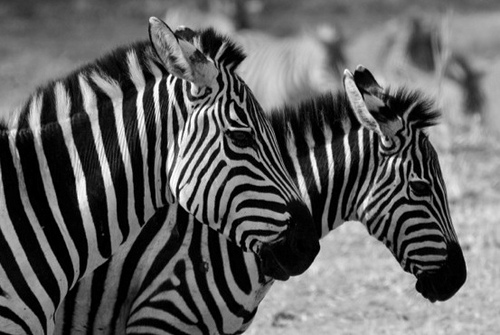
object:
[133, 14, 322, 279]
head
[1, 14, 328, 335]
zebra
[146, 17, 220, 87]
ear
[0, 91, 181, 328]
neck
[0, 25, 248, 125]
mane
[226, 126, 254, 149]
eye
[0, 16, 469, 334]
zebras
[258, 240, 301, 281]
mouth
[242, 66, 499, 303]
grass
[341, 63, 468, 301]
head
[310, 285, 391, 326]
ground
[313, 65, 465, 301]
zebra